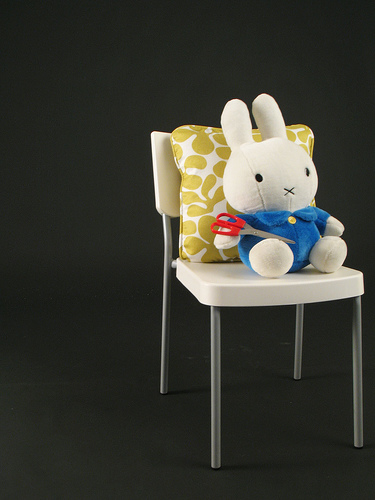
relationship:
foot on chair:
[244, 238, 301, 281] [151, 132, 375, 472]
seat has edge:
[176, 244, 372, 306] [208, 274, 369, 290]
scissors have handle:
[210, 213, 302, 247] [212, 211, 250, 240]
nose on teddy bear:
[282, 185, 299, 198] [212, 94, 349, 279]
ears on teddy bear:
[219, 94, 296, 149] [212, 94, 349, 279]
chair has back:
[151, 132, 375, 472] [152, 130, 195, 215]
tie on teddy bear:
[257, 207, 321, 225] [212, 94, 349, 279]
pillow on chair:
[178, 125, 319, 260] [151, 132, 375, 472]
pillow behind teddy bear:
[178, 125, 319, 260] [212, 94, 349, 279]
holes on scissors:
[221, 215, 235, 223] [210, 213, 302, 247]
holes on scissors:
[215, 224, 233, 233] [210, 213, 302, 247]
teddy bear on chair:
[212, 94, 349, 279] [151, 132, 375, 472]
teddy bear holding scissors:
[212, 94, 349, 279] [210, 213, 302, 247]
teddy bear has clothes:
[212, 94, 349, 279] [231, 207, 329, 273]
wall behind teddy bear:
[1, 1, 375, 296] [212, 94, 349, 279]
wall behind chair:
[1, 1, 375, 296] [151, 132, 375, 472]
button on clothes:
[287, 215, 299, 225] [231, 207, 329, 273]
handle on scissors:
[212, 211, 250, 240] [210, 213, 302, 247]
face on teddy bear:
[225, 147, 320, 213] [212, 94, 349, 279]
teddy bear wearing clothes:
[212, 94, 349, 279] [231, 207, 329, 273]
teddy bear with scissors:
[212, 94, 349, 279] [210, 213, 302, 247]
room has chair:
[1, 3, 374, 495] [151, 132, 375, 472]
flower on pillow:
[186, 180, 222, 216] [178, 125, 319, 260]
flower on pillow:
[288, 125, 315, 152] [178, 125, 319, 260]